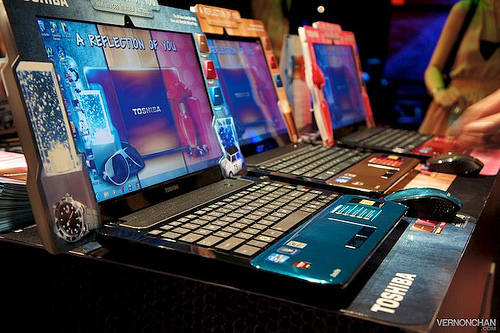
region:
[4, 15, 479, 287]
three Toshiba laptop computers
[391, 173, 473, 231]
blue and black computer mouse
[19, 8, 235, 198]
computer screen with a colorful background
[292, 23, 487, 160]
red Toshiba laptop computer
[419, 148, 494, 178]
black computer mouse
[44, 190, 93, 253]
small black clock with white numbers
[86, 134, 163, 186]
sunglasses on a computer screen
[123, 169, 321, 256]
black computer keyboard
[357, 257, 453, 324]
white Toshiba logo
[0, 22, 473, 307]
computers on a display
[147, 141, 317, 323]
a laptop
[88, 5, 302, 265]
a laptop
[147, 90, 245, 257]
a laptop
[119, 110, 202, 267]
a laptop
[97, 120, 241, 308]
a laptop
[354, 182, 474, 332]
toshiba mouse pad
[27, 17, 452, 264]
three toshiba laptops on a table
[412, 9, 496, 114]
lady standing at the end of the table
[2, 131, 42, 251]
papers behind laptop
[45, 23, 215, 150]
screensaver says "a reflection of you"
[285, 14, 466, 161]
red toshiba laptop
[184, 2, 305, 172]
orange toshiba laptop on table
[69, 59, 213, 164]
reflection of toshiba laptop as a screensaver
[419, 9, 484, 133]
lady with purse over shoulder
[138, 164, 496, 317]
matching blue toshiba laptop and mouse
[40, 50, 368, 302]
black laptop computer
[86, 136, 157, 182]
picture of aviator-style sunglasses on computer screen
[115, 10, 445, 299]
three laptop computers sitting side-by-side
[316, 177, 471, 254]
computer mouse sitting next to laptop computer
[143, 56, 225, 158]
a picture of perfume on the computer screen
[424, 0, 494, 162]
a person standing next to the table of computers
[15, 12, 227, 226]
a Toshiba brand laptop computer screen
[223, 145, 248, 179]
a picture of a white mini cooper in the lower right corner of computer screen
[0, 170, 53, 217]
a stack of papers sitting behind a laptop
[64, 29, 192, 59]
"A reflection of you" stated on the laptop computer screen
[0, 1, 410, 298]
a toshiba laptop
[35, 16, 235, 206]
a screen on a laptop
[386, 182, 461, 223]
a blue and black mouse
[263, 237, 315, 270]
stickers on a laptop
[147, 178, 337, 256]
a keyboard on a laptop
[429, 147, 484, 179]
a dark grey laptop mouse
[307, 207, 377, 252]
a touch pad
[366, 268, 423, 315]
white words saying Toshiba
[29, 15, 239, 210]
a light computer screen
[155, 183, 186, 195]
a computer logo